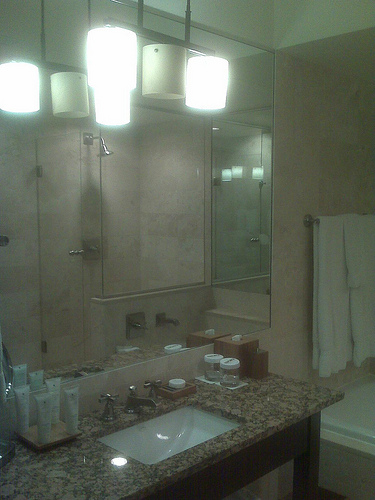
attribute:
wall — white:
[269, 54, 373, 401]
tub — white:
[319, 376, 373, 496]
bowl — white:
[93, 402, 241, 464]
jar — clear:
[219, 356, 238, 386]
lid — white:
[201, 352, 224, 364]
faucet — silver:
[100, 377, 164, 422]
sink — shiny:
[94, 401, 242, 464]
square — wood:
[11, 417, 79, 451]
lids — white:
[202, 350, 239, 369]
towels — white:
[311, 212, 373, 372]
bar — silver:
[302, 210, 318, 227]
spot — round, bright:
[110, 455, 127, 466]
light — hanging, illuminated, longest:
[82, 24, 136, 126]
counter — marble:
[2, 373, 343, 497]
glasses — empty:
[202, 354, 239, 386]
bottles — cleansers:
[11, 375, 80, 443]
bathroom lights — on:
[81, 27, 228, 124]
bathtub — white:
[313, 388, 374, 451]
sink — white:
[103, 398, 240, 464]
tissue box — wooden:
[217, 332, 258, 389]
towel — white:
[311, 210, 351, 370]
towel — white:
[338, 207, 367, 288]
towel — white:
[345, 258, 373, 367]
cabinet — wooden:
[221, 452, 319, 499]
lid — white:
[219, 355, 240, 365]